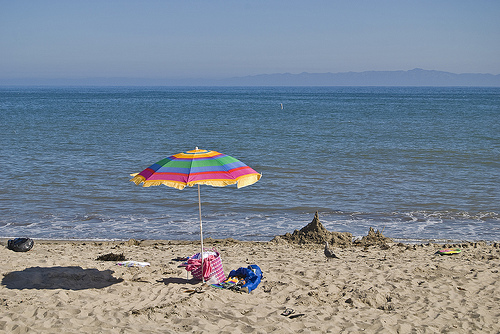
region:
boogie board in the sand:
[436, 236, 463, 262]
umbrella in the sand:
[137, 141, 241, 298]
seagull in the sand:
[314, 238, 348, 262]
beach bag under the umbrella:
[183, 242, 226, 285]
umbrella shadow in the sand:
[29, 255, 95, 293]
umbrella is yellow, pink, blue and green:
[162, 139, 249, 196]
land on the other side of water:
[231, 63, 395, 100]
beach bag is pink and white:
[197, 249, 239, 280]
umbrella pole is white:
[188, 180, 210, 241]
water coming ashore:
[85, 215, 140, 240]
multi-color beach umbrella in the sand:
[126, 140, 263, 285]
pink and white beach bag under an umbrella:
[186, 248, 226, 287]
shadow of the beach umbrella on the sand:
[1, 264, 125, 291]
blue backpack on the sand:
[219, 261, 262, 290]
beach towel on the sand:
[117, 256, 152, 269]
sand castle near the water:
[276, 210, 391, 247]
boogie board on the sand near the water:
[438, 240, 462, 256]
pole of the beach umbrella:
[197, 182, 205, 281]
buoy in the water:
[277, 100, 285, 110]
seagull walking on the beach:
[321, 238, 341, 263]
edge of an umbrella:
[188, 149, 232, 190]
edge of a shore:
[339, 220, 397, 287]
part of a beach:
[348, 249, 397, 308]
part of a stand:
[176, 185, 222, 257]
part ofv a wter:
[341, 125, 394, 190]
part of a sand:
[285, 195, 357, 247]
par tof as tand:
[338, 237, 390, 304]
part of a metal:
[177, 197, 222, 259]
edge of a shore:
[386, 215, 432, 260]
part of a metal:
[236, 260, 258, 289]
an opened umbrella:
[129, 142, 264, 297]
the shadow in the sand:
[1, 257, 126, 303]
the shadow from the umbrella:
[4, 263, 123, 293]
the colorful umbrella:
[130, 143, 263, 190]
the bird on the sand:
[317, 237, 341, 263]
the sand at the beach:
[286, 252, 488, 332]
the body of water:
[7, 88, 497, 249]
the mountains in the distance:
[16, 51, 498, 94]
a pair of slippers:
[278, 305, 308, 320]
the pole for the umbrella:
[191, 182, 214, 290]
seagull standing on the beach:
[315, 234, 342, 268]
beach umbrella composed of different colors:
[128, 143, 268, 193]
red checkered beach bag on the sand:
[186, 251, 226, 289]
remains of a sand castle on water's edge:
[284, 210, 386, 252]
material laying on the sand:
[116, 258, 149, 271]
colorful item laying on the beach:
[433, 245, 467, 257]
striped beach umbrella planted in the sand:
[128, 144, 265, 283]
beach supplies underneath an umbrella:
[126, 143, 266, 293]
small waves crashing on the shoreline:
[4, 210, 489, 232]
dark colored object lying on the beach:
[4, 231, 38, 258]